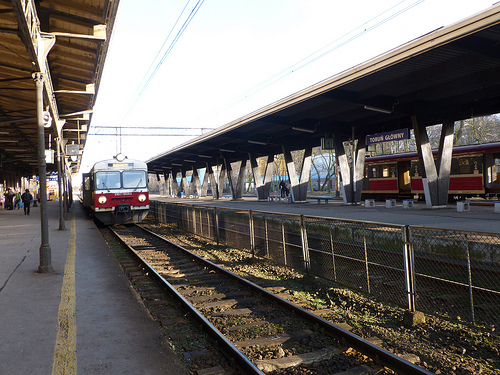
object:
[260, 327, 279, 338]
rocks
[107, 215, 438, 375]
track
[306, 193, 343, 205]
bench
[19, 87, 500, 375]
terminal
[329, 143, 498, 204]
train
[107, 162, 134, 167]
sign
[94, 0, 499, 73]
sky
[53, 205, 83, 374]
line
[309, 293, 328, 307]
grass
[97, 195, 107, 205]
headlights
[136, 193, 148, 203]
light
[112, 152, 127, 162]
light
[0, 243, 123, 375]
platform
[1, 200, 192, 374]
sidewalk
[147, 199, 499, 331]
fence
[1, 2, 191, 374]
station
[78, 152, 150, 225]
train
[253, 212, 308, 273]
fence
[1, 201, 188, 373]
ground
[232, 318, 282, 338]
gravel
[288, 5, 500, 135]
structure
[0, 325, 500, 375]
ground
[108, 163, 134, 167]
destination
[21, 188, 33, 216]
commuters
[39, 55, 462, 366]
suburbs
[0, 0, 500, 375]
city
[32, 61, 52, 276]
pole